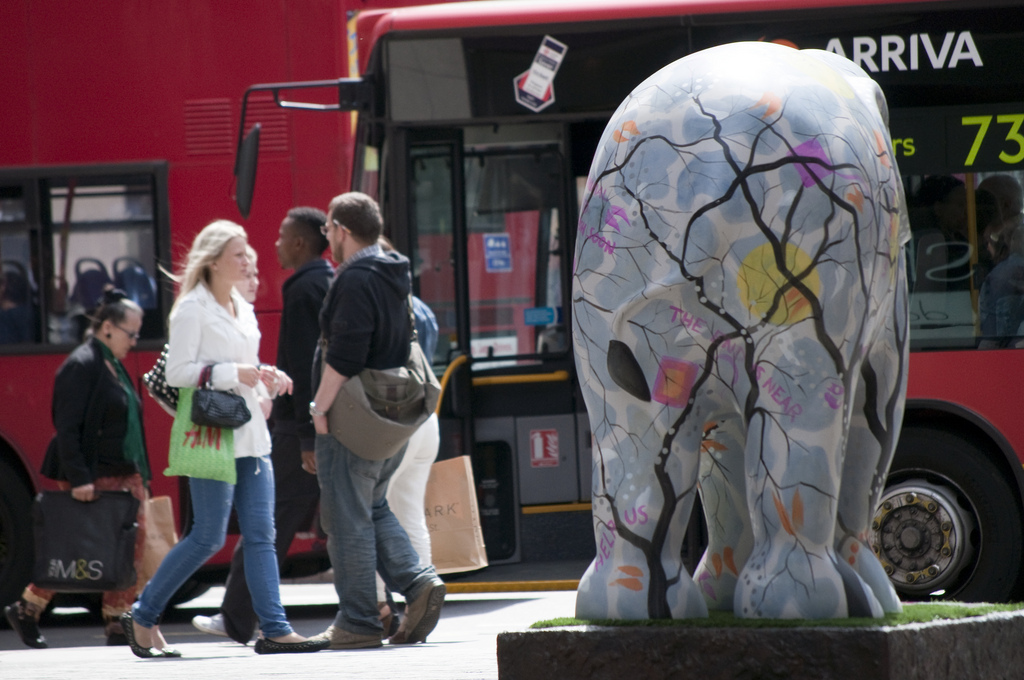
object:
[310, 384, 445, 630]
pants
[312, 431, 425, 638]
grey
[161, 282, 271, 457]
jacket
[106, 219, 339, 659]
woman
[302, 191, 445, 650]
person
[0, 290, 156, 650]
person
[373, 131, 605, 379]
window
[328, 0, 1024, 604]
bus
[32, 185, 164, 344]
window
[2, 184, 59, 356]
window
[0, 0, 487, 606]
bus